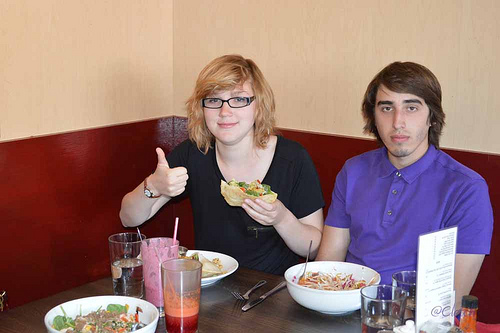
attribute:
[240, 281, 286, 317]
knife — shiny, silver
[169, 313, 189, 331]
liquid — red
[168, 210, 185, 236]
straw — plastic